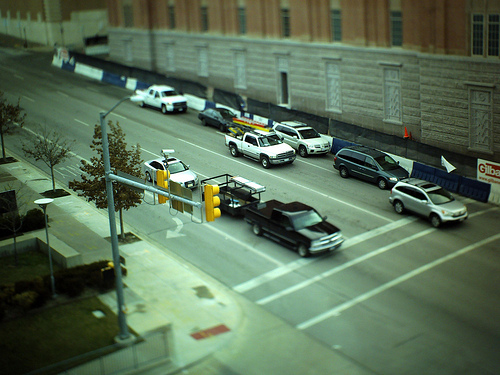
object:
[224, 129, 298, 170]
car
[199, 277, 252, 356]
intersection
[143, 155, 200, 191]
car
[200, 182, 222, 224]
light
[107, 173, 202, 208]
pole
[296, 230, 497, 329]
line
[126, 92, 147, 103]
light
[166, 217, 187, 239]
arrow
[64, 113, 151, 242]
tree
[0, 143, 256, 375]
sidewalk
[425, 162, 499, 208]
barriers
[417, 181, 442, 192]
sun roof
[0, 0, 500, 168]
building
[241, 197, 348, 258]
car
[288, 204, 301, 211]
black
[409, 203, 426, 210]
gray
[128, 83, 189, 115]
car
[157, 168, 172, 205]
traffic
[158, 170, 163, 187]
yellow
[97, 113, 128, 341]
pole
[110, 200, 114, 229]
gray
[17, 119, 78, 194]
tree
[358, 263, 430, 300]
white lines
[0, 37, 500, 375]
road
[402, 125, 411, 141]
cone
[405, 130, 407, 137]
orange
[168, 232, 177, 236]
white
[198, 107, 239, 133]
car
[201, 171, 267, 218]
black cart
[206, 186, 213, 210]
yellow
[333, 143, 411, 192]
car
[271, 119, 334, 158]
car